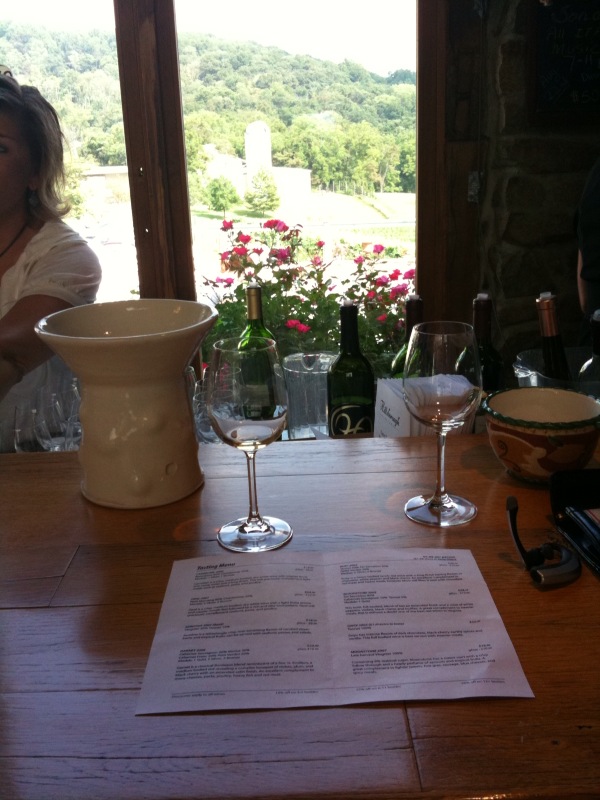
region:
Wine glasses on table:
[179, 329, 499, 557]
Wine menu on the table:
[127, 512, 544, 728]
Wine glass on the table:
[184, 305, 322, 577]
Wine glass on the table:
[382, 306, 503, 540]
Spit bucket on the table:
[15, 266, 241, 539]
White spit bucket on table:
[27, 273, 227, 521]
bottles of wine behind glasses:
[242, 281, 405, 431]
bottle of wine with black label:
[315, 300, 397, 433]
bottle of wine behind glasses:
[315, 291, 392, 437]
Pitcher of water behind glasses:
[271, 333, 368, 440]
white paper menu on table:
[177, 548, 517, 700]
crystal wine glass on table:
[184, 330, 300, 551]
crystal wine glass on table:
[377, 316, 479, 556]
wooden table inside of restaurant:
[1, 443, 589, 796]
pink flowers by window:
[232, 204, 388, 377]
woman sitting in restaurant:
[1, 78, 79, 389]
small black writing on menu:
[185, 562, 329, 598]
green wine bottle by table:
[244, 291, 275, 420]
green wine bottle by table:
[325, 295, 375, 421]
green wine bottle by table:
[389, 299, 426, 395]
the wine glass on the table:
[208, 336, 297, 555]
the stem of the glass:
[244, 449, 267, 528]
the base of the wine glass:
[213, 515, 295, 551]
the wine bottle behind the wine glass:
[236, 286, 277, 430]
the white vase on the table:
[35, 296, 220, 508]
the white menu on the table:
[134, 548, 536, 716]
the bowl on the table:
[486, 387, 599, 486]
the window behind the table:
[173, 0, 415, 315]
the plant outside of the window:
[201, 217, 421, 374]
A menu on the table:
[133, 534, 535, 714]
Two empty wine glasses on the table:
[199, 316, 487, 555]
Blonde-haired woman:
[0, 69, 102, 358]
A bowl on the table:
[482, 378, 598, 481]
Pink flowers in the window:
[205, 206, 418, 361]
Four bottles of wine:
[331, 290, 582, 438]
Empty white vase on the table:
[29, 295, 220, 511]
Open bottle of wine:
[232, 287, 278, 414]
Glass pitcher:
[283, 343, 343, 447]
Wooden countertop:
[3, 429, 598, 796]